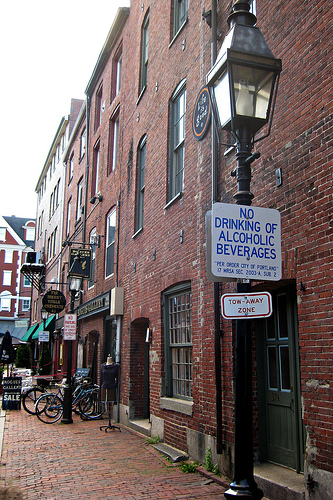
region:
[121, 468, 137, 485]
part of a floor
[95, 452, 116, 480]
part f a floor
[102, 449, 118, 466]
part fo a floor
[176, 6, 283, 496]
Black color metal pole with street light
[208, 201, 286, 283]
Square shape white color board with metal pole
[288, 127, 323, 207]
Red color bricks of the building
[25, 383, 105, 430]
Cycle parked near the building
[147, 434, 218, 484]
Small plants near the building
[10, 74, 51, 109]
Sky with clouds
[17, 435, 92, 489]
Side walk near the building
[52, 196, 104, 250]
Black color light attached to the buildings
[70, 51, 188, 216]
Lot of glass windows in the building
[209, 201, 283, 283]
White sign on a light post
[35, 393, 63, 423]
Back tire on a bike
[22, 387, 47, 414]
Tire on a bicycle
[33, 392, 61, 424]
rear tire on a bike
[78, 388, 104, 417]
front tire on a bicycle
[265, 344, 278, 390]
Window on a door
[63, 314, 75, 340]
No parking sign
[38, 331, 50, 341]
A sign posted up on a light post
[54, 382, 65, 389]
Seat on a bicycle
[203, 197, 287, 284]
blue and white sign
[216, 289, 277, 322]
red and white sign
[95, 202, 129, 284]
window on the side of the building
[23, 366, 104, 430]
a row of bikes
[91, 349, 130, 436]
mannequin on the sidewalk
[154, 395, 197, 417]
windowsill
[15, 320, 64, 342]
two green awnings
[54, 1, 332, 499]
the building is made of brick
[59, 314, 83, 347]
sign on a pole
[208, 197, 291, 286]
white and blue sign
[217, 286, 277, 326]
red and white sign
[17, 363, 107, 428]
a row of bikes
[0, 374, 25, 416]
sign on the sidewalk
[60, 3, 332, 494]
building is made of red brick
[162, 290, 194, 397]
lines on the window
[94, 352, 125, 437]
mannequin on the sidewalk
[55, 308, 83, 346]
sign on he pole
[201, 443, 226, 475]
weeds growing alongside the building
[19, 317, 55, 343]
two green awnings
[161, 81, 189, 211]
Window of a building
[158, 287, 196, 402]
Window of a building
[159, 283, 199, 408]
Window of a building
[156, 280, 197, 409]
Window of a red building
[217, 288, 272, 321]
Red and white sign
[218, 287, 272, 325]
Red and white street sign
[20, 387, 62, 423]
Tires of a couple bikes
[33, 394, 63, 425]
Tire of a bike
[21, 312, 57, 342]
two awnings on the building